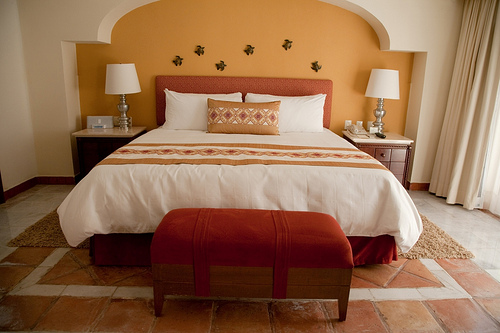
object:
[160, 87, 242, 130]
pillow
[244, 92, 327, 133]
pillow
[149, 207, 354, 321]
seat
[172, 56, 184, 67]
turtle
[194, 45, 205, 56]
turtle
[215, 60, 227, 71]
turtle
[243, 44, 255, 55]
turtle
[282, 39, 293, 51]
turtle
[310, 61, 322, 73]
turtle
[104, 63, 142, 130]
lamp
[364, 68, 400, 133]
lamp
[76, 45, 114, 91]
shade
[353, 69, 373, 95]
shade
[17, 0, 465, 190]
background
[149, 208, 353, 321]
ottoman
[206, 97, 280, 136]
pillows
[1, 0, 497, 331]
room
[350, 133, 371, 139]
cord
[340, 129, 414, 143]
surface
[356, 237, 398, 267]
bedskirt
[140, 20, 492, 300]
sunlight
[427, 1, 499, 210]
curtains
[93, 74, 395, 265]
bed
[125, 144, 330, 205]
sheets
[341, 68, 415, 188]
left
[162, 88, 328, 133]
two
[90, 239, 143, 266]
tuft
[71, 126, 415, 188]
two nightstands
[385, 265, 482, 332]
tiles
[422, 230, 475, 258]
rug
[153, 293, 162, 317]
leg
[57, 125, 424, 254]
bedspread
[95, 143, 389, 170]
carpet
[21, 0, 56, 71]
wall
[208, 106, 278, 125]
design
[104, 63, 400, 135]
pair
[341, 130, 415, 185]
table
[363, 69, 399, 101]
lampshade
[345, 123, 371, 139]
telephone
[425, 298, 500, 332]
piece